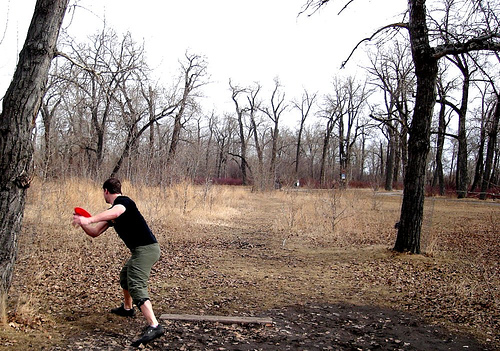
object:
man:
[72, 179, 163, 345]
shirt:
[108, 196, 156, 250]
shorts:
[118, 242, 161, 307]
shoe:
[110, 304, 134, 315]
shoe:
[133, 323, 165, 344]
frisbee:
[74, 207, 88, 219]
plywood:
[159, 313, 272, 327]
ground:
[0, 183, 495, 344]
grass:
[28, 174, 72, 223]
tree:
[296, 0, 497, 253]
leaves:
[77, 270, 90, 282]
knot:
[29, 37, 45, 53]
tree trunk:
[0, 1, 69, 275]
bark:
[410, 142, 419, 165]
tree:
[261, 80, 282, 182]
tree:
[228, 80, 250, 163]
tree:
[164, 51, 215, 174]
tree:
[66, 60, 174, 178]